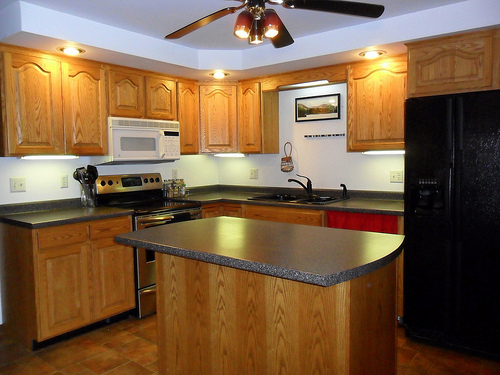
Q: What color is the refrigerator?
A: Black.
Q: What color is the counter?
A: Gray.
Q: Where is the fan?
A: The ceiling.